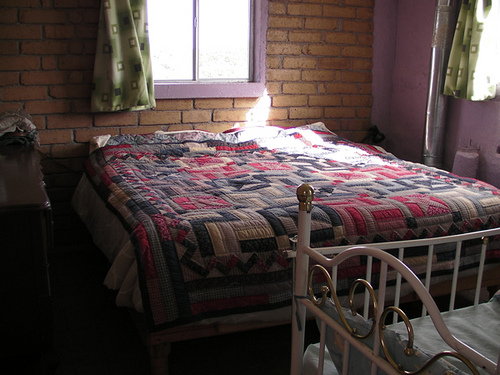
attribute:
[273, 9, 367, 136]
wall — brick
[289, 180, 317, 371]
post — gold